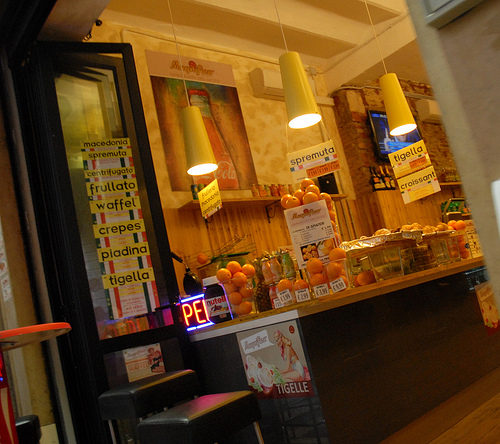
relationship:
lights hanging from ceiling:
[272, 7, 321, 138] [202, 3, 401, 62]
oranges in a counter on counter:
[217, 260, 255, 324] [189, 257, 489, 342]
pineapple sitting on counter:
[253, 257, 274, 312] [189, 257, 489, 342]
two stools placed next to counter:
[96, 367, 271, 441] [189, 257, 489, 342]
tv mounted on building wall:
[368, 108, 426, 160] [337, 86, 456, 180]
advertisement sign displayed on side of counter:
[233, 317, 316, 398] [189, 257, 489, 342]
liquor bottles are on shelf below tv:
[368, 163, 402, 191] [368, 108, 426, 160]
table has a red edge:
[1, 320, 73, 441] [2, 322, 74, 342]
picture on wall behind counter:
[145, 48, 262, 191] [189, 257, 489, 342]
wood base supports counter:
[191, 319, 497, 438] [189, 257, 489, 342]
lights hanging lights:
[276, 7, 320, 130] [276, 7, 320, 130]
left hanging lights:
[177, 99, 222, 179] [276, 7, 320, 130]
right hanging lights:
[377, 59, 419, 141] [276, 7, 320, 130]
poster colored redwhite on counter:
[285, 203, 344, 264] [189, 257, 489, 342]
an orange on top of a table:
[355, 267, 375, 289] [1, 320, 73, 441]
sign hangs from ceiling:
[389, 137, 443, 206] [202, 3, 401, 62]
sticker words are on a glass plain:
[84, 137, 158, 317] [49, 50, 180, 340]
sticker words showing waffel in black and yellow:
[84, 137, 158, 317] [92, 197, 142, 211]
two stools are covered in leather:
[96, 367, 271, 441] [175, 387, 261, 426]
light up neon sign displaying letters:
[177, 293, 218, 332] [184, 301, 208, 323]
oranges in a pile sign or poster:
[217, 260, 255, 324] [285, 203, 344, 264]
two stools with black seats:
[96, 367, 271, 441] [103, 371, 235, 428]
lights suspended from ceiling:
[276, 7, 320, 130] [202, 3, 401, 62]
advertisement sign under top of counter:
[233, 317, 316, 398] [189, 257, 489, 342]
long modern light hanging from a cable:
[163, 1, 220, 177] [160, 1, 195, 103]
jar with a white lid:
[202, 273, 234, 323] [203, 274, 220, 289]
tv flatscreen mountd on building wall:
[368, 108, 426, 160] [337, 86, 456, 180]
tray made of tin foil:
[344, 228, 424, 248] [398, 228, 421, 246]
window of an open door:
[49, 50, 180, 340] [33, 39, 186, 366]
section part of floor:
[445, 415, 472, 439] [419, 387, 498, 442]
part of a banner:
[477, 303, 495, 326] [475, 281, 497, 331]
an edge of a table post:
[4, 396, 21, 432] [1, 348, 23, 441]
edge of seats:
[127, 390, 153, 441] [103, 371, 235, 428]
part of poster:
[355, 276, 402, 298] [285, 203, 344, 264]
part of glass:
[75, 64, 119, 123] [52, 54, 135, 138]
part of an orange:
[355, 276, 402, 298] [355, 267, 375, 289]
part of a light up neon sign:
[181, 294, 193, 308] [177, 293, 218, 332]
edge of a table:
[35, 321, 69, 338] [1, 320, 73, 441]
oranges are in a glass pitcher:
[217, 260, 255, 324] [222, 275, 255, 317]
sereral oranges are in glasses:
[275, 248, 345, 300] [280, 269, 347, 287]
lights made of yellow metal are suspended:
[272, 7, 321, 138] [165, 1, 389, 48]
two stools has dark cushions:
[96, 367, 271, 441] [105, 376, 268, 424]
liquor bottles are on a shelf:
[368, 163, 402, 191] [365, 187, 437, 204]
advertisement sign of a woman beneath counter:
[235, 317, 314, 398] [189, 257, 489, 342]